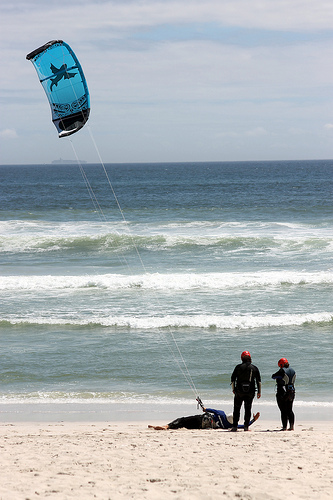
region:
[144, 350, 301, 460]
the people on the beach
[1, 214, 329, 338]
the waves on the ocean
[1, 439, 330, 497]
the sand at the ocean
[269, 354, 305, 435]
a woman wearing a wet suit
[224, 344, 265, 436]
a man wearing a wet suit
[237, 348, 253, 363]
a man wearing a red helmet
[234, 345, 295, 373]
two people wearing red helmets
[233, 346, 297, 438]
two people wearing wet suits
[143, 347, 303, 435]
three people wearing wet suits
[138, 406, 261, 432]
a man lying on the beach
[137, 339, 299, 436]
three people in wet suits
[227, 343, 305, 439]
two people in wet suits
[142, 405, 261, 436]
a man lying on the sand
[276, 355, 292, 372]
a woman wearing a red helmet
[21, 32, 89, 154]
a blue and black para-sail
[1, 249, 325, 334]
waves on the ocean water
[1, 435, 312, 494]
a very sandy beach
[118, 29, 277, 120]
Sky is blue color.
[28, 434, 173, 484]
Sand is brown color.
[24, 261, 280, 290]
Waves are white color.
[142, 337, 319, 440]
Three people are in sand.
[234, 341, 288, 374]
Helmet is red color.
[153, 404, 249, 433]
One man is lying in sand.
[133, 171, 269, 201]
Water is blue color.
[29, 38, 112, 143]
Kite is blue and black color.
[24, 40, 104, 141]
Kite is flying in air.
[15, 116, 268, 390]
Day time picture.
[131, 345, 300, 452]
Three people on a beach.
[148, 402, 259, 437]
A person laying on a beach.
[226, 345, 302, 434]
Two people standing on a beach.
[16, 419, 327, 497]
Tracks on a beach.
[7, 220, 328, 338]
White foam on the waves.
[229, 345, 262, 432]
Person standing on left wearing red helmet.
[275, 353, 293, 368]
Person standing on right wearing red helmet.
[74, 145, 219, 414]
White lines attached to kite.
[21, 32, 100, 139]
Kite for kitesurfing.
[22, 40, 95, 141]
A blue and black kite.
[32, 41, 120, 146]
blue parachute in sky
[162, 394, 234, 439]
person lying on ground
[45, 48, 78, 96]
black design on parachute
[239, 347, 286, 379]
people wear red helmets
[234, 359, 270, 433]
man wears black wetsuit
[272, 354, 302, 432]
woman wears blue wetsuit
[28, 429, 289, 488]
people on light brown sand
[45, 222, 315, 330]
white waves on water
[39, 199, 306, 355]
water is light blue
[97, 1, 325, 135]
sky has layered clouds